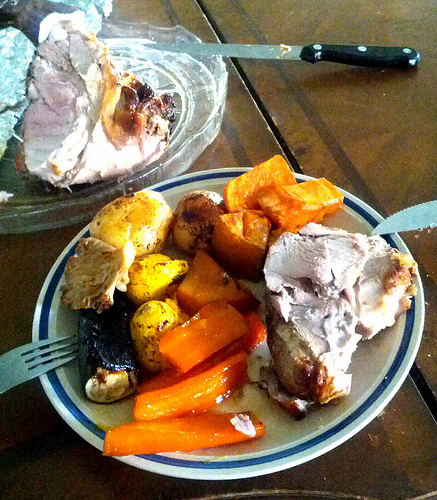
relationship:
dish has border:
[39, 152, 420, 457] [391, 349, 409, 372]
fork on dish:
[0, 332, 86, 380] [39, 152, 420, 457]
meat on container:
[26, 31, 168, 195] [0, 8, 229, 213]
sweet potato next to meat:
[258, 178, 353, 230] [269, 223, 411, 409]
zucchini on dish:
[72, 305, 138, 400] [39, 152, 420, 457]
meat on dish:
[269, 223, 411, 409] [39, 152, 420, 457]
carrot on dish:
[103, 408, 277, 462] [39, 152, 420, 457]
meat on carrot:
[231, 415, 263, 441] [103, 408, 277, 462]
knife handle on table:
[304, 36, 420, 73] [6, 3, 435, 488]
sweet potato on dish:
[218, 216, 260, 274] [39, 152, 420, 457]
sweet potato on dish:
[227, 162, 300, 191] [39, 152, 420, 457]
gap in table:
[238, 70, 291, 144] [6, 3, 435, 488]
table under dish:
[6, 3, 435, 488] [39, 152, 420, 457]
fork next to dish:
[0, 332, 86, 380] [39, 152, 420, 457]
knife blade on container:
[146, 33, 304, 67] [0, 8, 229, 213]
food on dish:
[69, 251, 121, 297] [39, 152, 420, 457]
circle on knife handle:
[313, 41, 323, 54] [304, 36, 420, 73]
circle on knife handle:
[356, 45, 367, 53] [304, 36, 420, 73]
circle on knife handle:
[403, 44, 416, 55] [304, 36, 420, 73]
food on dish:
[95, 203, 166, 252] [39, 152, 420, 457]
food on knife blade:
[279, 41, 291, 55] [146, 33, 304, 67]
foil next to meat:
[1, 30, 25, 144] [26, 31, 168, 195]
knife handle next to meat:
[304, 36, 420, 73] [26, 31, 168, 195]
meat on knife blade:
[269, 223, 411, 409] [146, 33, 304, 67]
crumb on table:
[428, 351, 433, 363] [6, 3, 435, 488]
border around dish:
[391, 349, 409, 372] [39, 152, 420, 457]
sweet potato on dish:
[258, 178, 353, 230] [39, 152, 420, 457]